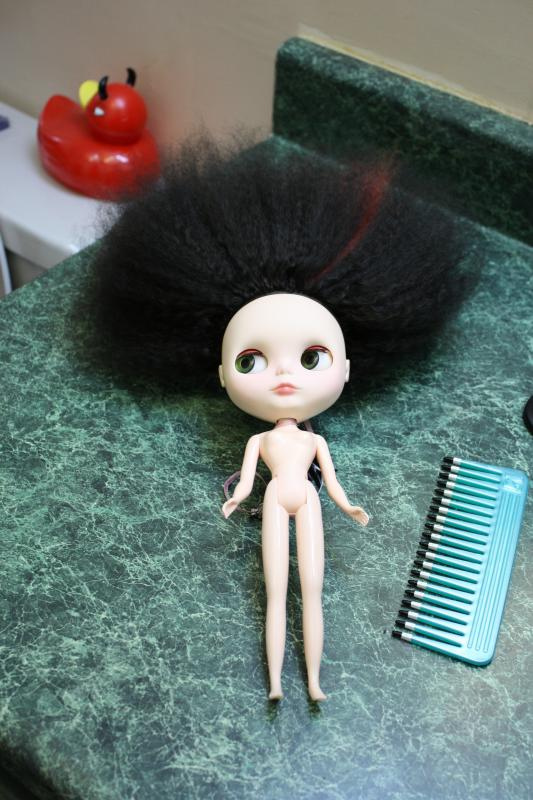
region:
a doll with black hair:
[63, 116, 481, 722]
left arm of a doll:
[311, 432, 382, 541]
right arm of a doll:
[210, 432, 267, 524]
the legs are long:
[254, 477, 343, 714]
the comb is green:
[391, 454, 531, 674]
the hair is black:
[65, 125, 500, 433]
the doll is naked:
[52, 119, 501, 727]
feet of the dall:
[257, 675, 333, 716]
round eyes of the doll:
[228, 341, 334, 376]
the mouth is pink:
[270, 375, 301, 398]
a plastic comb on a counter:
[380, 418, 531, 669]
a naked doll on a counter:
[217, 289, 370, 715]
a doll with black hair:
[84, 144, 470, 412]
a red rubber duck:
[40, 58, 147, 196]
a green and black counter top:
[6, 238, 530, 640]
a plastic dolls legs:
[258, 514, 334, 719]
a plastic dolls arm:
[208, 424, 266, 518]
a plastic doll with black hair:
[83, 144, 488, 708]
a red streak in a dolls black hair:
[305, 151, 402, 273]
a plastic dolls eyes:
[220, 338, 338, 381]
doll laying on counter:
[58, 180, 530, 708]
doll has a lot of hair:
[65, 195, 496, 396]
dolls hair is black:
[57, 117, 524, 385]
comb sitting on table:
[390, 444, 527, 671]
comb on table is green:
[385, 446, 530, 673]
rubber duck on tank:
[25, 61, 169, 211]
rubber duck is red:
[27, 59, 164, 205]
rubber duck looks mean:
[25, 59, 167, 209]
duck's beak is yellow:
[76, 74, 101, 112]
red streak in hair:
[319, 142, 400, 280]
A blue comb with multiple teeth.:
[389, 455, 531, 665]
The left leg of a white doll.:
[292, 503, 330, 704]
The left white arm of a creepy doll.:
[318, 433, 373, 529]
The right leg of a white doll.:
[259, 508, 290, 705]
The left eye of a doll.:
[298, 341, 332, 374]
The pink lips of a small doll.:
[272, 379, 299, 397]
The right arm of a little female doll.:
[221, 432, 259, 518]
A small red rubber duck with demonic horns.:
[34, 66, 168, 200]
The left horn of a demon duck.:
[123, 65, 139, 87]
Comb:
[389, 440, 527, 668]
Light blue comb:
[389, 444, 526, 671]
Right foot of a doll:
[303, 683, 329, 703]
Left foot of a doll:
[260, 678, 285, 703]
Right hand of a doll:
[344, 501, 372, 530]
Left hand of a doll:
[213, 492, 240, 522]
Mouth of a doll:
[267, 379, 298, 397]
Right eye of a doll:
[296, 341, 333, 376]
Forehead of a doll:
[251, 303, 313, 337]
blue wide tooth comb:
[382, 446, 529, 686]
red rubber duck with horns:
[21, 57, 175, 220]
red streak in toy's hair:
[255, 143, 416, 305]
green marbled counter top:
[21, 432, 248, 777]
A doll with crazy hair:
[105, 174, 441, 413]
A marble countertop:
[7, 441, 196, 715]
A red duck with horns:
[6, 52, 159, 275]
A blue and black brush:
[381, 460, 517, 590]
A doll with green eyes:
[224, 323, 341, 381]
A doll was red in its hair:
[300, 159, 411, 283]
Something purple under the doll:
[204, 427, 337, 540]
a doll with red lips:
[220, 378, 311, 419]